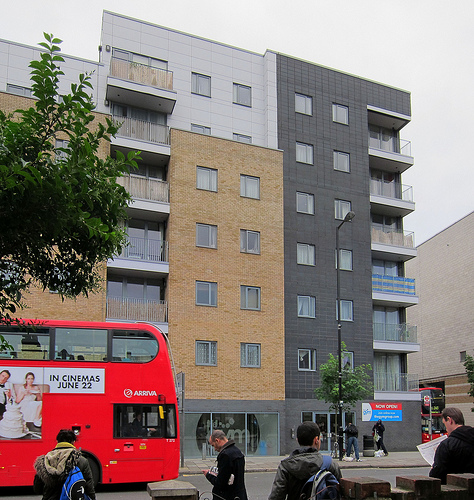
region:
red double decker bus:
[1, 314, 183, 481]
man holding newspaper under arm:
[200, 427, 250, 496]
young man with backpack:
[31, 426, 98, 498]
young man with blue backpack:
[265, 419, 345, 498]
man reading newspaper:
[414, 405, 470, 481]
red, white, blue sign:
[359, 400, 404, 423]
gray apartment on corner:
[267, 48, 428, 452]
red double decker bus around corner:
[421, 383, 446, 443]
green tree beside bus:
[3, 60, 142, 357]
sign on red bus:
[3, 362, 107, 437]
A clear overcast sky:
[378, 23, 425, 62]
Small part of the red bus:
[74, 399, 107, 418]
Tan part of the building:
[202, 315, 231, 334]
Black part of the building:
[311, 268, 334, 295]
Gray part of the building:
[211, 51, 238, 73]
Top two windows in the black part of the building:
[288, 89, 353, 130]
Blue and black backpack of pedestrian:
[59, 468, 88, 498]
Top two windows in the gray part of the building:
[189, 65, 264, 112]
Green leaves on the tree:
[30, 178, 76, 214]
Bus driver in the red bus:
[128, 412, 150, 436]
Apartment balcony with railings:
[99, 41, 178, 112]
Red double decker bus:
[0, 316, 182, 489]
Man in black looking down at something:
[200, 429, 253, 498]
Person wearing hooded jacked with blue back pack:
[34, 427, 99, 498]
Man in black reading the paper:
[412, 406, 472, 480]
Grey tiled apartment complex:
[277, 52, 431, 396]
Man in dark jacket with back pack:
[267, 421, 342, 498]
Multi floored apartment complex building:
[0, 2, 425, 351]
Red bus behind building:
[391, 375, 451, 452]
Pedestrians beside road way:
[0, 402, 473, 498]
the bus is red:
[3, 303, 187, 493]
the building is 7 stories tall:
[1, 0, 424, 458]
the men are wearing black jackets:
[193, 397, 471, 498]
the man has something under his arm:
[200, 460, 260, 498]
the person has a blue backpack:
[36, 420, 96, 495]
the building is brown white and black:
[0, 0, 411, 461]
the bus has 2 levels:
[1, 313, 208, 493]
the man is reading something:
[412, 396, 471, 497]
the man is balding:
[198, 423, 241, 452]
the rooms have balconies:
[358, 107, 416, 398]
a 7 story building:
[2, 2, 426, 458]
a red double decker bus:
[1, 314, 180, 492]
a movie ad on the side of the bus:
[0, 368, 106, 439]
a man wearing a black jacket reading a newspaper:
[417, 407, 472, 484]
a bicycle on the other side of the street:
[332, 430, 342, 460]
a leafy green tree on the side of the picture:
[1, 142, 140, 316]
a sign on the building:
[363, 402, 402, 420]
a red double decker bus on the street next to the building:
[420, 387, 447, 445]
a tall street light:
[333, 209, 357, 460]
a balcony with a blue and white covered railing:
[370, 253, 416, 299]